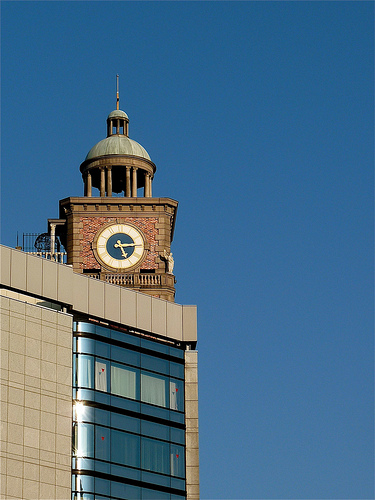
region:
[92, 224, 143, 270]
clock face on a clock tower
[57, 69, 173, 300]
clock tower area of the building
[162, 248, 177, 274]
statue on the clock tower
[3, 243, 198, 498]
bulding with many windows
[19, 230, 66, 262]
metal fence area next to the clock tower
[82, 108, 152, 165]
two domes on top of the clock tower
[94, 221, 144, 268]
the time is 5:15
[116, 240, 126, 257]
the hour hand on the clock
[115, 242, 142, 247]
the minute hand on the clock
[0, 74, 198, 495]
tall building with a clock tower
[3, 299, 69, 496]
tan concrete building with brown lines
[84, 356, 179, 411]
windows on the side of a building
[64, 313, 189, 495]
blue section on a tan building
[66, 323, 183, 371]
black decorative trim in a blue section of building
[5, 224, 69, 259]
iron fencing on the roof of the building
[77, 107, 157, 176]
two domes near the top of the building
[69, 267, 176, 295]
brown railing near the top of the building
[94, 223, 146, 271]
clock face with Roman numerals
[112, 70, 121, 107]
empty flag pole at tip of building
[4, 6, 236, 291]
dark blue sky behind the building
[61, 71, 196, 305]
clock tower on top of building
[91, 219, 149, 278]
clock face with roman numerals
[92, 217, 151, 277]
blue and white clock face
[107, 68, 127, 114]
lightning rod on top of tower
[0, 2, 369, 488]
clear blue sunny sky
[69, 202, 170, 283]
side facing brick wall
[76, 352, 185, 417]
row of curtained windows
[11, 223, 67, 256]
iron railing on top of building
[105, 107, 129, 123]
small dome on clock tower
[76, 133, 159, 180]
large dome on clock tower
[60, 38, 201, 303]
a clock tower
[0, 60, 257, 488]
a new building juxtaposed with an older building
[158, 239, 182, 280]
a small statue on the tower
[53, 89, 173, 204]
a bell tower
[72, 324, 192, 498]
blue windows of a building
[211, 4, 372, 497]
empty blue sky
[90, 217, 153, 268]
a clock with a blue face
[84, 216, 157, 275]
a clock with Roman numerals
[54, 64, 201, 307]
a tower with a dome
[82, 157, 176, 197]
pillars holding up a dome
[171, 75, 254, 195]
the sky is clear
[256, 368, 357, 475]
the sky is clear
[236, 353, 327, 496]
the sky is clear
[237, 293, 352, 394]
the sky is clear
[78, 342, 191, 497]
blue glass window of the building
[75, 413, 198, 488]
blue glass window of the building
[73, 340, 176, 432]
blue glass window of the building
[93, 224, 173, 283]
clock's hands are gold